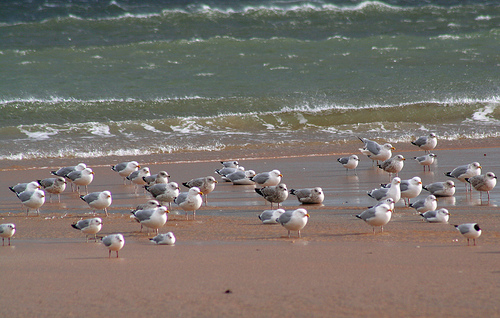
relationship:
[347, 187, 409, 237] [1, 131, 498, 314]
bird on beach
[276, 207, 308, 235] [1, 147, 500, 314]
birds at beach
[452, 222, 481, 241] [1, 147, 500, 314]
birds at beach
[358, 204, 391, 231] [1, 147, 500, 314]
birds at beach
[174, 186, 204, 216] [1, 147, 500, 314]
birds at beach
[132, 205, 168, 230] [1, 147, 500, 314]
birds at beach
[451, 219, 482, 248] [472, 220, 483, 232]
bird with face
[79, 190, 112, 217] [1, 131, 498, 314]
bird on beach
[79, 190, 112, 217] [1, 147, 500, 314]
bird standing on beach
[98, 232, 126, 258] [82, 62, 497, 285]
bird on beach